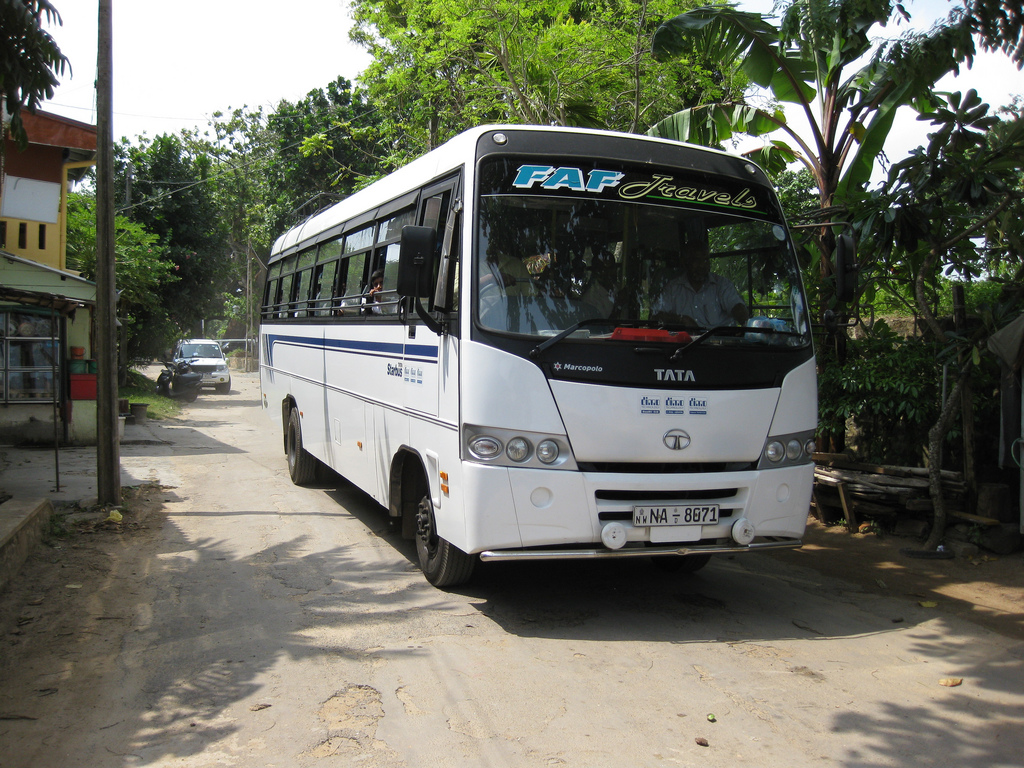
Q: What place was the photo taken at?
A: It was taken at the street.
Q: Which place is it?
A: It is a street.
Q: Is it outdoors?
A: Yes, it is outdoors.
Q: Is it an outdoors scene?
A: Yes, it is outdoors.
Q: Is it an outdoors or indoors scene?
A: It is outdoors.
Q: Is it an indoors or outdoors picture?
A: It is outdoors.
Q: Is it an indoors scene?
A: No, it is outdoors.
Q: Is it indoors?
A: No, it is outdoors.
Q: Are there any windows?
A: Yes, there is a window.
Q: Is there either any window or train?
A: Yes, there is a window.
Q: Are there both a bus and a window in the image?
A: Yes, there are both a window and a bus.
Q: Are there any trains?
A: No, there are no trains.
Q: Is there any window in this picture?
A: Yes, there is a window.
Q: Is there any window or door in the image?
A: Yes, there is a window.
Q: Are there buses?
A: Yes, there is a bus.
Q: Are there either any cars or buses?
A: Yes, there is a bus.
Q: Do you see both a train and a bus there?
A: No, there is a bus but no trains.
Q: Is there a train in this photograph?
A: No, there are no trains.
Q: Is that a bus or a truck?
A: That is a bus.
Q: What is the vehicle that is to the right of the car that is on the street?
A: The vehicle is a bus.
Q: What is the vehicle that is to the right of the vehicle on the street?
A: The vehicle is a bus.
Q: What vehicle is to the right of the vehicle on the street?
A: The vehicle is a bus.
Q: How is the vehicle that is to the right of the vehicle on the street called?
A: The vehicle is a bus.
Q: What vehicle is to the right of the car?
A: The vehicle is a bus.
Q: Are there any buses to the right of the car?
A: Yes, there is a bus to the right of the car.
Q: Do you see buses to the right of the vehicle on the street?
A: Yes, there is a bus to the right of the car.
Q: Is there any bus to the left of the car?
A: No, the bus is to the right of the car.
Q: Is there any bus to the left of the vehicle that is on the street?
A: No, the bus is to the right of the car.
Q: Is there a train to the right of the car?
A: No, there is a bus to the right of the car.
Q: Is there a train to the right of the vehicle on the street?
A: No, there is a bus to the right of the car.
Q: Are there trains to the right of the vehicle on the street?
A: No, there is a bus to the right of the car.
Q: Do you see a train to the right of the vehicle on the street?
A: No, there is a bus to the right of the car.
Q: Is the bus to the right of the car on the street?
A: Yes, the bus is to the right of the car.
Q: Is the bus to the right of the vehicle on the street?
A: Yes, the bus is to the right of the car.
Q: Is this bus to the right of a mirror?
A: No, the bus is to the right of the car.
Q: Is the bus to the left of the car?
A: No, the bus is to the right of the car.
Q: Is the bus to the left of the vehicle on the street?
A: No, the bus is to the right of the car.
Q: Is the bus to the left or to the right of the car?
A: The bus is to the right of the car.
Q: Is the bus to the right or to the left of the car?
A: The bus is to the right of the car.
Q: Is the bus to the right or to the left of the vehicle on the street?
A: The bus is to the right of the car.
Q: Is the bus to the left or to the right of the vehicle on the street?
A: The bus is to the right of the car.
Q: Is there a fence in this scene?
A: No, there are no fences.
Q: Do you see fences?
A: No, there are no fences.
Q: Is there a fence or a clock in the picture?
A: No, there are no fences or clocks.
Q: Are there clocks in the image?
A: No, there are no clocks.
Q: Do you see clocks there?
A: No, there are no clocks.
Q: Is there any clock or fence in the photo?
A: No, there are no clocks or fences.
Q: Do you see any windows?
A: Yes, there is a window.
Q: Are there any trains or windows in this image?
A: Yes, there is a window.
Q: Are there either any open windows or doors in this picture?
A: Yes, there is an open window.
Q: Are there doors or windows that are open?
A: Yes, the window is open.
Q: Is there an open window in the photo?
A: Yes, there is an open window.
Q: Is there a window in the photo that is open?
A: Yes, there is a window that is open.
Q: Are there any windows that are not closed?
A: Yes, there is a open window.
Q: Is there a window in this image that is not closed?
A: Yes, there is a open window.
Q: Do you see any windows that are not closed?
A: Yes, there is a open window.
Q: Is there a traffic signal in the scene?
A: No, there are no traffic lights.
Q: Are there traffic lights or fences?
A: No, there are no traffic lights or fences.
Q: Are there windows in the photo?
A: Yes, there is a window.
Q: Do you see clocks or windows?
A: Yes, there is a window.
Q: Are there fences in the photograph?
A: No, there are no fences.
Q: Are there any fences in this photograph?
A: No, there are no fences.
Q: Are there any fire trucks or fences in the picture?
A: No, there are no fences or fire trucks.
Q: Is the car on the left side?
A: Yes, the car is on the left of the image.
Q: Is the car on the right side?
A: No, the car is on the left of the image.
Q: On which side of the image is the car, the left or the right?
A: The car is on the left of the image.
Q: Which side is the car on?
A: The car is on the left of the image.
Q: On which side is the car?
A: The car is on the left of the image.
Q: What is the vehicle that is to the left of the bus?
A: The vehicle is a car.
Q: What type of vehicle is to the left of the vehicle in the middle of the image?
A: The vehicle is a car.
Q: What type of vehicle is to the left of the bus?
A: The vehicle is a car.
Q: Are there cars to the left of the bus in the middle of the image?
A: Yes, there is a car to the left of the bus.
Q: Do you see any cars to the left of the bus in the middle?
A: Yes, there is a car to the left of the bus.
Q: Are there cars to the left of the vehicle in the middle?
A: Yes, there is a car to the left of the bus.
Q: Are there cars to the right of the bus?
A: No, the car is to the left of the bus.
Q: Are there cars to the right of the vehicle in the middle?
A: No, the car is to the left of the bus.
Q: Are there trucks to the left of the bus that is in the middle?
A: No, there is a car to the left of the bus.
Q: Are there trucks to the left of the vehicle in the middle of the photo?
A: No, there is a car to the left of the bus.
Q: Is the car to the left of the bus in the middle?
A: Yes, the car is to the left of the bus.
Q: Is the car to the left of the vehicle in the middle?
A: Yes, the car is to the left of the bus.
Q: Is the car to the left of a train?
A: No, the car is to the left of the bus.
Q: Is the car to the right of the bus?
A: No, the car is to the left of the bus.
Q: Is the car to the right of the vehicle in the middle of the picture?
A: No, the car is to the left of the bus.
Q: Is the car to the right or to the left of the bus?
A: The car is to the left of the bus.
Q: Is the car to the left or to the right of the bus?
A: The car is to the left of the bus.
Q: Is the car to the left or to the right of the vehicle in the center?
A: The car is to the left of the bus.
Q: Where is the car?
A: The car is on the street.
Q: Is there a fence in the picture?
A: No, there are no fences.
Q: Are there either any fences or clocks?
A: No, there are no fences or clocks.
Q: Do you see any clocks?
A: No, there are no clocks.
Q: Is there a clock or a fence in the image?
A: No, there are no clocks or fences.